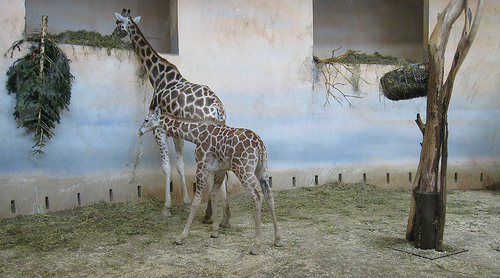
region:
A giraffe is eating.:
[98, 5, 166, 50]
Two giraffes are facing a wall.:
[105, 8, 282, 246]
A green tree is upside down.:
[4, 15, 74, 155]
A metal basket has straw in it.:
[379, 62, 432, 98]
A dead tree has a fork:
[407, 0, 484, 248]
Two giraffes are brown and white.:
[112, 7, 284, 252]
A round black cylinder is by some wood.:
[405, 186, 455, 249]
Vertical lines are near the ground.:
[0, 166, 496, 213]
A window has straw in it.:
[311, 0, 422, 67]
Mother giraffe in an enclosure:
[109, 7, 230, 234]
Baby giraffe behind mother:
[138, 106, 282, 255]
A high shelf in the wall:
[23, 0, 177, 53]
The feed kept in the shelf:
[24, 30, 135, 46]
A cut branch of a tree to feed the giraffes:
[6, 17, 71, 154]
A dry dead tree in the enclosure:
[406, 1, 480, 248]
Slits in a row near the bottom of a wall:
[9, 173, 485, 215]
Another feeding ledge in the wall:
[312, 1, 429, 63]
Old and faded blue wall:
[0, 0, 499, 214]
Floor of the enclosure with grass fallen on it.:
[0, 180, 496, 275]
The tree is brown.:
[405, 0, 487, 250]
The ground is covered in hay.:
[36, 235, 136, 274]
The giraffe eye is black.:
[143, 116, 152, 125]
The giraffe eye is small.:
[143, 115, 153, 126]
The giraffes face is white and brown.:
[136, 105, 169, 135]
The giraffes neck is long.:
[108, 4, 178, 83]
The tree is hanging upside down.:
[4, 10, 72, 151]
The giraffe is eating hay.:
[109, 8, 141, 42]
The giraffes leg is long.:
[155, 126, 178, 218]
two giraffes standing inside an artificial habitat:
[4, 3, 492, 269]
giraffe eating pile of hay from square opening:
[100, 11, 235, 117]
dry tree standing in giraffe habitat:
[397, 2, 490, 248]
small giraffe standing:
[135, 104, 287, 246]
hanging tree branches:
[6, 14, 74, 152]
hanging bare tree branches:
[316, 42, 377, 111]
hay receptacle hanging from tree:
[382, 59, 442, 99]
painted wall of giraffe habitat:
[276, 100, 411, 180]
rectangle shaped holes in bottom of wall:
[4, 180, 146, 214]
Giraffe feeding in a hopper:
[102, 3, 184, 103]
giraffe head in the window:
[100, 4, 151, 51]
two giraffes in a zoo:
[98, 5, 301, 258]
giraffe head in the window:
[106, 8, 148, 48]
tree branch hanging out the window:
[3, 8, 67, 139]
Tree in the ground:
[408, 98, 463, 264]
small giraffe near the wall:
[125, 97, 291, 239]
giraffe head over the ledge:
[99, 10, 142, 52]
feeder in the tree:
[366, 53, 446, 108]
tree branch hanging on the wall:
[9, 13, 71, 155]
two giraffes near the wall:
[109, 17, 299, 257]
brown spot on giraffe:
[242, 138, 250, 151]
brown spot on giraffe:
[232, 139, 244, 158]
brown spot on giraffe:
[232, 153, 241, 165]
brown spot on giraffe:
[242, 159, 253, 175]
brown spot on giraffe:
[171, 118, 182, 128]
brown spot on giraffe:
[185, 118, 197, 130]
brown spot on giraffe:
[194, 95, 202, 111]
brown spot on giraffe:
[176, 88, 187, 109]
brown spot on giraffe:
[148, 62, 158, 77]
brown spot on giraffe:
[146, 45, 151, 60]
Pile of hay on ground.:
[275, 165, 400, 217]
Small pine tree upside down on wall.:
[0, 9, 85, 163]